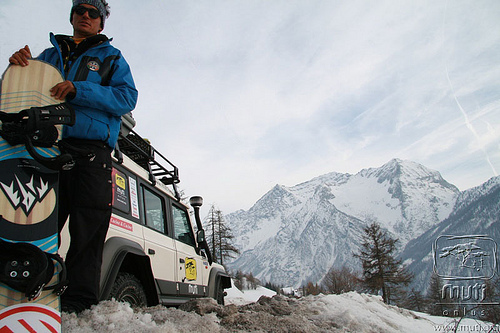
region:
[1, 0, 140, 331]
The man is holding a snowboard.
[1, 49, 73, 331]
The snowboard is colorful.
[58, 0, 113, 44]
The man is wearing a cap.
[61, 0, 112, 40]
The man is wearing sunglasses.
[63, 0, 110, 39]
The sunglasses are dark.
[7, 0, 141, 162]
The man is wearing a jacket.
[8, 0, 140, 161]
The man's jacket is blue and black.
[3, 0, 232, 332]
The man is standing in snow.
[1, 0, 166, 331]
The man is wearing pants.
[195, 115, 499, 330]
The mountains are snow covered.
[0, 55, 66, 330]
Snowboard with mountain graphic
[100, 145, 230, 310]
white jeep with roofrack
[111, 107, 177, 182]
roofrack for carrying luggage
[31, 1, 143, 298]
man in blue coat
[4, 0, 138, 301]
man in snowboarding gear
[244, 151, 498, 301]
large mountains in background covered with snow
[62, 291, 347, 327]
"dirty snow" on the ground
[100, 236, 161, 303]
plastic wheel whells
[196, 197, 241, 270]
thinly-leafed trees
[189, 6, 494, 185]
cloudy sky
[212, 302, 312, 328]
black patch of snow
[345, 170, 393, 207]
snow on top of the mountain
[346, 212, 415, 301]
green tree on the snow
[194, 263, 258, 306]
black bumper on truck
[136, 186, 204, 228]
windows in side of jeep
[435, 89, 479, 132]
white streaks in the sky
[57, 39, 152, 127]
black and blue ski jacket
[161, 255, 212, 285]
yellow sign on side of van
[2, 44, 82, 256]
large blue and tan snow board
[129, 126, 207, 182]
black frame on top of van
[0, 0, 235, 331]
young man holding a snowboard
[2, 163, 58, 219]
his snowboard has mountain on it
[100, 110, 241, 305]
he has car behind him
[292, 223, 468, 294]
there is a trees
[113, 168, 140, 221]
stickers on the car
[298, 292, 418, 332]
snow on the ground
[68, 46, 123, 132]
he has a blue coat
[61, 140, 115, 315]
black snow pants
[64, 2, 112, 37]
has a snow hat on sun glasses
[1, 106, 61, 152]
has a foot strap on his snowboard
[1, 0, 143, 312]
a man holding a snowboard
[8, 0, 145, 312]
man wears a blue jacket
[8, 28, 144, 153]
blue winter jacket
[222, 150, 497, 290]
a mountain covered with snow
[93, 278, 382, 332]
snow on side a car is dirty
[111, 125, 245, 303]
a white car on the snow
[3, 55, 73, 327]
snowboard is white and blue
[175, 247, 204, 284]
a yellow picture on car's door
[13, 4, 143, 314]
man wears black pants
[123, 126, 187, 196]
a rack on roof of car